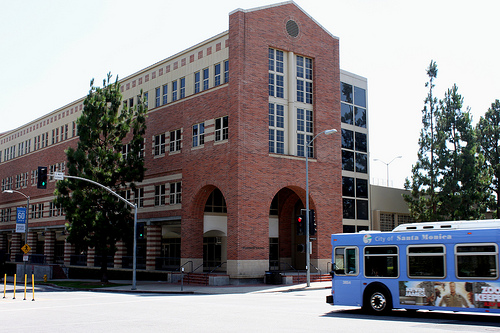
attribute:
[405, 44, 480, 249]
tree — green, tall 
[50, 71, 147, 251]
leaves — green 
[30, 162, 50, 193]
light — black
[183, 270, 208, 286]
stairs — short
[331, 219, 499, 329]
bus — blue 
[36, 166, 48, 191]
light — green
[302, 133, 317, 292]
pole — gray 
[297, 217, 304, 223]
light — Red 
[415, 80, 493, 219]
tree — tall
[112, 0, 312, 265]
building — brick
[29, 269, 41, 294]
pole — yellow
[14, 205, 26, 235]
flag — white, blue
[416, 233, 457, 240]
letter — white 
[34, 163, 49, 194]
light — Green 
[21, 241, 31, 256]
sign — yellow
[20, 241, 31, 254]
sign — pedestrian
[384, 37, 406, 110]
sky — bright , white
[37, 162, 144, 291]
pole — metal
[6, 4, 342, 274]
building — large 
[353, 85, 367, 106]
window — dark 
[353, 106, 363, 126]
window — dark 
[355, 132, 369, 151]
window — dark 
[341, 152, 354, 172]
window — dark 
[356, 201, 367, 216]
window — dark 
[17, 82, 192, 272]
tree — Tall 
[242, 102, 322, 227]
building — arched 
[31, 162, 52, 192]
light — Black, metal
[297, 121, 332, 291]
street light — gray, tall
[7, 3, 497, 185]
sky — cloudy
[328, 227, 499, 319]
bus — blue , owned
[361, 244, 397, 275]
window — dark 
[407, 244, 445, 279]
window — dark 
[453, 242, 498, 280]
window — dark 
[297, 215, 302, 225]
light — red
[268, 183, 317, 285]
entryway — Arched 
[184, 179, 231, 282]
entryway — Arched 